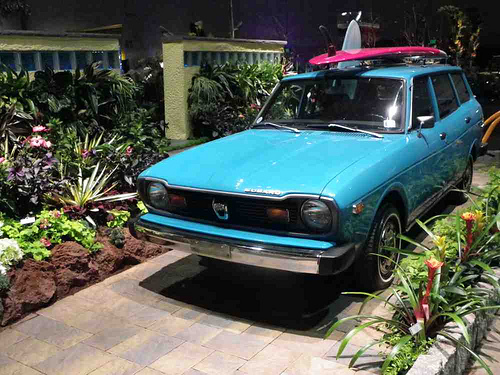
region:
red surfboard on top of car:
[305, 43, 448, 71]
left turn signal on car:
[263, 205, 292, 229]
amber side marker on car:
[350, 198, 367, 216]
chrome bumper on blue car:
[122, 209, 361, 279]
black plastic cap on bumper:
[304, 237, 362, 279]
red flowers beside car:
[410, 253, 455, 332]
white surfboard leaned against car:
[326, 17, 366, 102]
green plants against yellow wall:
[185, 60, 288, 116]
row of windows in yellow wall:
[3, 45, 122, 73]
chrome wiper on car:
[326, 122, 383, 142]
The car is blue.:
[224, 143, 341, 179]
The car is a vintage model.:
[132, 65, 430, 212]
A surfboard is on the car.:
[307, 44, 445, 69]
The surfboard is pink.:
[307, 44, 447, 66]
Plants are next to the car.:
[0, 70, 140, 168]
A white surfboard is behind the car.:
[341, 10, 364, 47]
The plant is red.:
[419, 265, 436, 319]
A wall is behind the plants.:
[167, 38, 186, 138]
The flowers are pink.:
[31, 125, 51, 145]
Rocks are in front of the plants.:
[52, 255, 94, 282]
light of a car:
[128, 167, 188, 212]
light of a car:
[283, 197, 353, 230]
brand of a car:
[198, 193, 248, 223]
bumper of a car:
[116, 207, 373, 270]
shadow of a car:
[203, 277, 341, 304]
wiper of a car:
[245, 116, 320, 146]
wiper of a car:
[314, 114, 405, 144]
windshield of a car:
[251, 70, 430, 134]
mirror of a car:
[413, 107, 444, 124]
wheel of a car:
[340, 184, 432, 288]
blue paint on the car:
[111, 40, 493, 311]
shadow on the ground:
[132, 255, 348, 346]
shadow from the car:
[131, 248, 345, 350]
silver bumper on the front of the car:
[115, 207, 357, 299]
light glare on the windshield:
[381, 104, 399, 115]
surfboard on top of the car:
[280, 30, 477, 69]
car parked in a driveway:
[3, 21, 498, 372]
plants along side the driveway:
[321, 163, 498, 373]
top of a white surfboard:
[332, 16, 367, 43]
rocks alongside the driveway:
[1, 203, 151, 318]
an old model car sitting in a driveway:
[81, 23, 491, 325]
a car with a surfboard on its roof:
[111, 38, 488, 313]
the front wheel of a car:
[367, 205, 404, 285]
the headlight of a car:
[297, 193, 337, 235]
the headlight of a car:
[143, 177, 173, 211]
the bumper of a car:
[136, 210, 348, 276]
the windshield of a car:
[262, 83, 403, 134]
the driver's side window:
[412, 73, 434, 127]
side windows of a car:
[434, 68, 467, 119]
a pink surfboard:
[309, 36, 452, 63]